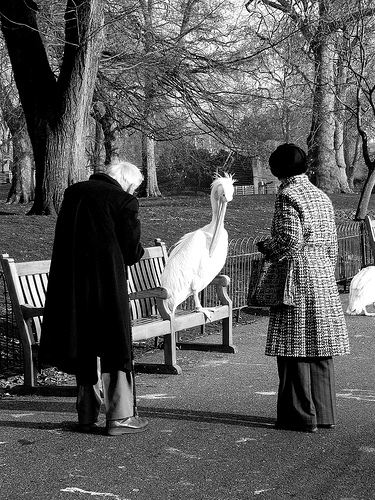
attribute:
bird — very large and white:
[149, 172, 243, 302]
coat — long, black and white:
[283, 265, 319, 316]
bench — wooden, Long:
[19, 287, 225, 306]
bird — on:
[203, 193, 233, 201]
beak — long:
[205, 196, 227, 257]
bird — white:
[151, 157, 249, 330]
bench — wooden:
[10, 236, 241, 401]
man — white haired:
[36, 154, 149, 435]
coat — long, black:
[34, 171, 146, 387]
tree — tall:
[244, 2, 372, 188]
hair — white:
[109, 160, 148, 192]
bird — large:
[163, 165, 233, 319]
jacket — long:
[41, 171, 151, 369]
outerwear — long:
[33, 171, 146, 379]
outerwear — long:
[262, 171, 352, 362]